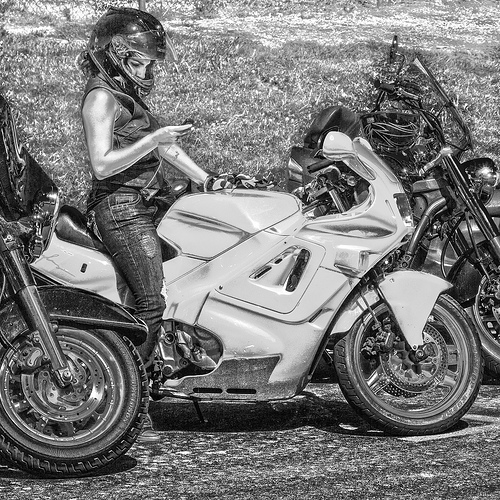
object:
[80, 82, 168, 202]
jacket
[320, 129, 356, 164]
mirror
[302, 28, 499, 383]
motorbike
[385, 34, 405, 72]
mirror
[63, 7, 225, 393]
woman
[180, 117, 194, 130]
cellphone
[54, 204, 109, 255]
seat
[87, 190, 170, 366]
jeans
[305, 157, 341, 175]
handle bar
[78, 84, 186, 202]
snowboarder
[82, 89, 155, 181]
arm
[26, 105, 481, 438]
bike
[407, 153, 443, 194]
ground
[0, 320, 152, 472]
front tire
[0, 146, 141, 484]
motorcycle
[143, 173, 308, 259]
tank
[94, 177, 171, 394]
leg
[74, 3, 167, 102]
head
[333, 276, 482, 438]
tire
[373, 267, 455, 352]
fender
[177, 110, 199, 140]
object